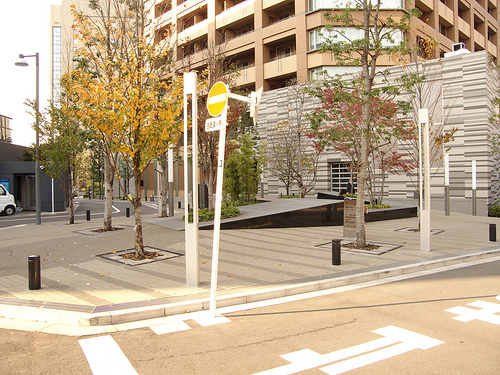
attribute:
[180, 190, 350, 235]
ramp — black, concrete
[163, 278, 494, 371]
pavement — white, painted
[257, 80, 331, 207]
tree — bare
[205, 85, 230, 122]
sign — shaped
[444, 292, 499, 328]
white line — painted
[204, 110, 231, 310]
sign post — white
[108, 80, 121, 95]
leaves — yellow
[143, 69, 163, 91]
leaves — yellow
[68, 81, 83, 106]
leaves — yellow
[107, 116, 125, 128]
leaves — yellow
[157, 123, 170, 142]
leaves — yellow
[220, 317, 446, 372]
paint — white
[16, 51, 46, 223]
light — tall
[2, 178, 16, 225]
car — white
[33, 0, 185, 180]
leaves — yellow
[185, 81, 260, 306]
sign — tall, street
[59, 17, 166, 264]
trees sidwalk — planted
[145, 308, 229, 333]
line — white, painted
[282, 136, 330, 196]
trees — bare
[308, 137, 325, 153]
flower — purplish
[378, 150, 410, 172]
flower — purplish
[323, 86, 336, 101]
flower — purplish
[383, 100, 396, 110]
flower — purplish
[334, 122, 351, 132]
flower — purplish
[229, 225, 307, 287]
street — adjacent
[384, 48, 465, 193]
tree — bare